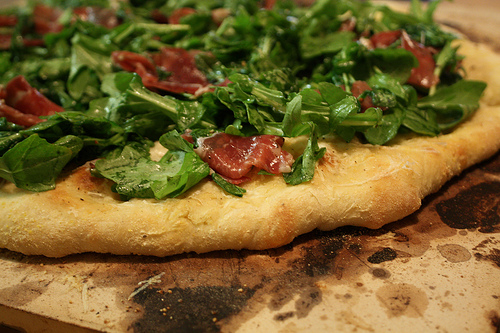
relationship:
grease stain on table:
[375, 281, 429, 321] [0, 155, 498, 331]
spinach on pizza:
[0, 134, 69, 192] [0, 1, 499, 258]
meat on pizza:
[189, 131, 295, 185] [0, 1, 499, 258]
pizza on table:
[0, 1, 499, 258] [0, 155, 498, 331]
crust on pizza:
[1, 41, 497, 258] [0, 1, 499, 258]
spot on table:
[128, 281, 262, 332] [0, 155, 498, 331]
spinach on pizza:
[92, 130, 213, 199] [0, 1, 499, 258]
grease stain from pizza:
[375, 281, 429, 321] [0, 1, 499, 258]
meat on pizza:
[115, 46, 231, 97] [0, 1, 499, 258]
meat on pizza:
[0, 75, 66, 128] [0, 1, 499, 258]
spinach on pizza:
[365, 72, 484, 145] [0, 1, 499, 258]